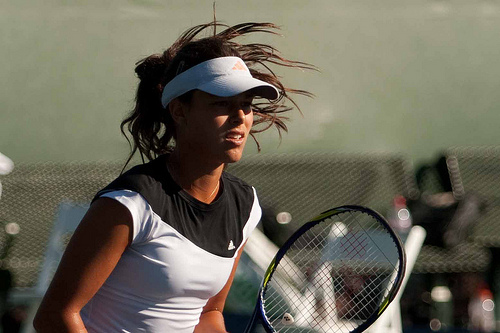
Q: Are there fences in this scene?
A: Yes, there is a fence.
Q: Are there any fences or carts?
A: Yes, there is a fence.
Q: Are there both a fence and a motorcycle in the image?
A: No, there is a fence but no motorcycles.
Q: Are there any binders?
A: No, there are no binders.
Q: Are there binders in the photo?
A: No, there are no binders.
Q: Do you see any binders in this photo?
A: No, there are no binders.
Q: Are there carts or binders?
A: No, there are no binders or carts.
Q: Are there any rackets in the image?
A: Yes, there is a racket.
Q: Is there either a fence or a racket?
A: Yes, there is a racket.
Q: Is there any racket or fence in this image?
A: Yes, there is a racket.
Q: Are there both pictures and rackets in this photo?
A: No, there is a racket but no pictures.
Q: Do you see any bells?
A: No, there are no bells.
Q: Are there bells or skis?
A: No, there are no bells or skis.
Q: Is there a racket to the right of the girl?
A: Yes, there is a racket to the right of the girl.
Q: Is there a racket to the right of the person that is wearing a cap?
A: Yes, there is a racket to the right of the girl.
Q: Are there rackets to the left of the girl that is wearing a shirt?
A: No, the racket is to the right of the girl.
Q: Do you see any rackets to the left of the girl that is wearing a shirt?
A: No, the racket is to the right of the girl.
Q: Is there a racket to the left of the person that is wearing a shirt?
A: No, the racket is to the right of the girl.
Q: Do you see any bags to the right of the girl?
A: No, there is a racket to the right of the girl.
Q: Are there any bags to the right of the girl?
A: No, there is a racket to the right of the girl.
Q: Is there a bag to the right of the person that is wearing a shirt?
A: No, there is a racket to the right of the girl.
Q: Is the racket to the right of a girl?
A: Yes, the racket is to the right of a girl.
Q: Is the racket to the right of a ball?
A: No, the racket is to the right of a girl.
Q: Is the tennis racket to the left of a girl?
A: No, the tennis racket is to the right of a girl.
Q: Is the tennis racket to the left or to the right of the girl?
A: The tennis racket is to the right of the girl.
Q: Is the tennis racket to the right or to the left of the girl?
A: The tennis racket is to the right of the girl.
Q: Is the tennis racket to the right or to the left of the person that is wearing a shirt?
A: The tennis racket is to the right of the girl.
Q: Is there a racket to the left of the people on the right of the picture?
A: Yes, there is a racket to the left of the people.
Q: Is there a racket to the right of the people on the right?
A: No, the racket is to the left of the people.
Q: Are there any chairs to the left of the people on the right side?
A: No, there is a racket to the left of the people.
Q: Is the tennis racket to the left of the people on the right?
A: Yes, the tennis racket is to the left of the people.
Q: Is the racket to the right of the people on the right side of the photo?
A: No, the racket is to the left of the people.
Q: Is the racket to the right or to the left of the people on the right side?
A: The racket is to the left of the people.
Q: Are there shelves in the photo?
A: No, there are no shelves.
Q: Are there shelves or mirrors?
A: No, there are no shelves or mirrors.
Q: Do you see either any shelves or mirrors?
A: No, there are no shelves or mirrors.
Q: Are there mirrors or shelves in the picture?
A: No, there are no shelves or mirrors.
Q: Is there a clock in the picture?
A: No, there are no clocks.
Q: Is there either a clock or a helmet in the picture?
A: No, there are no clocks or helmets.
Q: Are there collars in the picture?
A: Yes, there is a collar.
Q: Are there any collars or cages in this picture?
A: Yes, there is a collar.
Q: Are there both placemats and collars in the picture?
A: No, there is a collar but no placemats.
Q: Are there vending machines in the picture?
A: No, there are no vending machines.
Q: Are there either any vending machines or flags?
A: No, there are no vending machines or flags.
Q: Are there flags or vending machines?
A: No, there are no vending machines or flags.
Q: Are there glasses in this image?
A: No, there are no glasses.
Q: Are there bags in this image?
A: No, there are no bags.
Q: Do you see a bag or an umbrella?
A: No, there are no bags or umbrellas.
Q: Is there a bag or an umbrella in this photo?
A: No, there are no bags or umbrellas.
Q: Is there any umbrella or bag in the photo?
A: No, there are no bags or umbrellas.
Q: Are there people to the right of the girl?
A: Yes, there are people to the right of the girl.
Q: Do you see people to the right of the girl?
A: Yes, there are people to the right of the girl.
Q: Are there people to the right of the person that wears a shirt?
A: Yes, there are people to the right of the girl.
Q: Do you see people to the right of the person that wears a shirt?
A: Yes, there are people to the right of the girl.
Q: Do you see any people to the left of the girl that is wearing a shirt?
A: No, the people are to the right of the girl.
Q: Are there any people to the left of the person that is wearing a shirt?
A: No, the people are to the right of the girl.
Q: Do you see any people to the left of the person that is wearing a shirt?
A: No, the people are to the right of the girl.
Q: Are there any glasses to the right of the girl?
A: No, there are people to the right of the girl.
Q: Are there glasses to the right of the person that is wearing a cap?
A: No, there are people to the right of the girl.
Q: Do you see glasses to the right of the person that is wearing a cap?
A: No, there are people to the right of the girl.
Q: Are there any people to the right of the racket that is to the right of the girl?
A: Yes, there are people to the right of the tennis racket.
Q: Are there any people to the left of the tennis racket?
A: No, the people are to the right of the tennis racket.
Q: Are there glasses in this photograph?
A: No, there are no glasses.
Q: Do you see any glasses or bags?
A: No, there are no glasses or bags.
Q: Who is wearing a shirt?
A: The girl is wearing a shirt.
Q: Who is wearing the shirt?
A: The girl is wearing a shirt.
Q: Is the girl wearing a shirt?
A: Yes, the girl is wearing a shirt.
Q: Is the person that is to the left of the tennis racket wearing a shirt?
A: Yes, the girl is wearing a shirt.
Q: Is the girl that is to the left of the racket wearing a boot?
A: No, the girl is wearing a shirt.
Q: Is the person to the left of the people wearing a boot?
A: No, the girl is wearing a shirt.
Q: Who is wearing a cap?
A: The girl is wearing a cap.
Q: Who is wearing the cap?
A: The girl is wearing a cap.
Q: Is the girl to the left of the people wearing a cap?
A: Yes, the girl is wearing a cap.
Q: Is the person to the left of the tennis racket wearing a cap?
A: Yes, the girl is wearing a cap.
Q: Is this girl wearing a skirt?
A: No, the girl is wearing a cap.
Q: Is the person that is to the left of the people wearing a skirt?
A: No, the girl is wearing a cap.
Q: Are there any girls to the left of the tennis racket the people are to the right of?
A: Yes, there is a girl to the left of the tennis racket.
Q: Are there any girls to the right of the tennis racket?
A: No, the girl is to the left of the tennis racket.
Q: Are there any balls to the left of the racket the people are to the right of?
A: No, there is a girl to the left of the tennis racket.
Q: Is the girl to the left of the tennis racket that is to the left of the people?
A: Yes, the girl is to the left of the tennis racket.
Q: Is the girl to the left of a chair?
A: No, the girl is to the left of the tennis racket.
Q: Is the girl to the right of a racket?
A: No, the girl is to the left of a racket.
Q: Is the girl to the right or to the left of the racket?
A: The girl is to the left of the racket.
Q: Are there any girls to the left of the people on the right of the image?
A: Yes, there is a girl to the left of the people.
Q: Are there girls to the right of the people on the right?
A: No, the girl is to the left of the people.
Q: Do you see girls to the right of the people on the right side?
A: No, the girl is to the left of the people.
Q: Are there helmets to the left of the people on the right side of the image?
A: No, there is a girl to the left of the people.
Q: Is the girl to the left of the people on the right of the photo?
A: Yes, the girl is to the left of the people.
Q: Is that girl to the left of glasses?
A: No, the girl is to the left of the people.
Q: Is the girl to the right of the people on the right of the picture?
A: No, the girl is to the left of the people.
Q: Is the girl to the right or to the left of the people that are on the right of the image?
A: The girl is to the left of the people.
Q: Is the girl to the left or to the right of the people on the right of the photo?
A: The girl is to the left of the people.